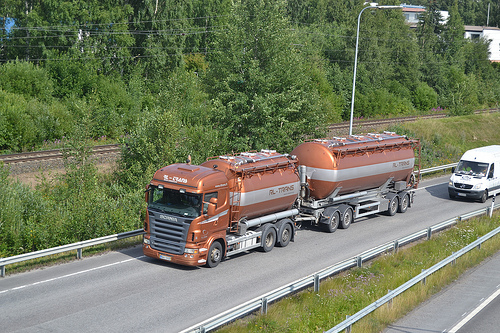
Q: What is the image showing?
A: It is showing a road.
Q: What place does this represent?
A: It represents the road.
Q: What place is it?
A: It is a road.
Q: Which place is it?
A: It is a road.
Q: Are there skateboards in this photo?
A: No, there are no skateboards.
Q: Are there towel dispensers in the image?
A: No, there are no towel dispensers.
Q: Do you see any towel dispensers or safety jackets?
A: No, there are no towel dispensers or safety jackets.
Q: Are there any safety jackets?
A: No, there are no safety jackets.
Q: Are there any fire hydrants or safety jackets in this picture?
A: No, there are no safety jackets or fire hydrants.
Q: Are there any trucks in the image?
A: Yes, there is a truck.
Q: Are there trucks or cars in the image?
A: Yes, there is a truck.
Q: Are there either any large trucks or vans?
A: Yes, there is a large truck.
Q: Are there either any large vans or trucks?
A: Yes, there is a large truck.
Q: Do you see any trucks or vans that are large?
A: Yes, the truck is large.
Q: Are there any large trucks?
A: Yes, there is a large truck.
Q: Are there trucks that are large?
A: Yes, there is a truck that is large.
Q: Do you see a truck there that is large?
A: Yes, there is a truck that is large.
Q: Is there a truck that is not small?
A: Yes, there is a large truck.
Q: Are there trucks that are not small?
A: Yes, there is a large truck.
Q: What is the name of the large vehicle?
A: The vehicle is a truck.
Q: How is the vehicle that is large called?
A: The vehicle is a truck.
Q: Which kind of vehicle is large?
A: The vehicle is a truck.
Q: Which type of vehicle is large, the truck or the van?
A: The truck is large.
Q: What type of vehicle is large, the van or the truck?
A: The truck is large.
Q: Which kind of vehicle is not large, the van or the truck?
A: The van is not large.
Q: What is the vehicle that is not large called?
A: The vehicle is a van.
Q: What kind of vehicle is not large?
A: The vehicle is a van.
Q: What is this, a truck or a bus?
A: This is a truck.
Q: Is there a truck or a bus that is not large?
A: No, there is a truck but it is large.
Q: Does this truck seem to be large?
A: Yes, the truck is large.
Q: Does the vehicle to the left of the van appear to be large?
A: Yes, the truck is large.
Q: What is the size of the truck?
A: The truck is large.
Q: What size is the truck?
A: The truck is large.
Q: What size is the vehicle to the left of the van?
A: The truck is large.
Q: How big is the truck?
A: The truck is large.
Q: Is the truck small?
A: No, the truck is large.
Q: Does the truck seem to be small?
A: No, the truck is large.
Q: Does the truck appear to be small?
A: No, the truck is large.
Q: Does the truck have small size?
A: No, the truck is large.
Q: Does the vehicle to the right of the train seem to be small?
A: No, the truck is large.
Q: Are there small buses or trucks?
A: No, there is a truck but it is large.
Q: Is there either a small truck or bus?
A: No, there is a truck but it is large.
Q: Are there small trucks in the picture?
A: No, there is a truck but it is large.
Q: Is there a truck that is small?
A: No, there is a truck but it is large.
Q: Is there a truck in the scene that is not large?
A: No, there is a truck but it is large.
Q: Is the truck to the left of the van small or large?
A: The truck is large.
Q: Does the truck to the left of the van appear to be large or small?
A: The truck is large.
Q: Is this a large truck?
A: Yes, this is a large truck.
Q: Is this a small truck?
A: No, this is a large truck.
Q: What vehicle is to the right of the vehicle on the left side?
A: The vehicle is a truck.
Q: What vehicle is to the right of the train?
A: The vehicle is a truck.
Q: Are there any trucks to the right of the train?
A: Yes, there is a truck to the right of the train.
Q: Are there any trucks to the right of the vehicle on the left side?
A: Yes, there is a truck to the right of the train.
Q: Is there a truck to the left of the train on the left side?
A: No, the truck is to the right of the train.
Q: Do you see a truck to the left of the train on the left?
A: No, the truck is to the right of the train.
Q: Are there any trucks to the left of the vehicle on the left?
A: No, the truck is to the right of the train.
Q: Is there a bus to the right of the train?
A: No, there is a truck to the right of the train.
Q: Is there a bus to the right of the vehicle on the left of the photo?
A: No, there is a truck to the right of the train.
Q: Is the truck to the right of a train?
A: Yes, the truck is to the right of a train.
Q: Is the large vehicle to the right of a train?
A: Yes, the truck is to the right of a train.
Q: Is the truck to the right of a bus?
A: No, the truck is to the right of a train.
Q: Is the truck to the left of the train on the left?
A: No, the truck is to the right of the train.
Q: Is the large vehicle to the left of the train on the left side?
A: No, the truck is to the right of the train.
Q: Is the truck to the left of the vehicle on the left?
A: No, the truck is to the right of the train.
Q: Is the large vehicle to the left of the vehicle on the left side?
A: No, the truck is to the right of the train.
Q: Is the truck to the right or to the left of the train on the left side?
A: The truck is to the right of the train.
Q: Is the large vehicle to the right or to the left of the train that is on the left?
A: The truck is to the right of the train.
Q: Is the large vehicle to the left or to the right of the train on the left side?
A: The truck is to the right of the train.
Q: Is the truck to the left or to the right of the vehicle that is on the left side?
A: The truck is to the right of the train.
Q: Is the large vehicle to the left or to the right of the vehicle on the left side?
A: The truck is to the right of the train.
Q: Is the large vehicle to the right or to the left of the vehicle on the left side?
A: The truck is to the right of the train.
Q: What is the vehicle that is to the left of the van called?
A: The vehicle is a truck.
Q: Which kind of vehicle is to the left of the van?
A: The vehicle is a truck.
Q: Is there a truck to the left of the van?
A: Yes, there is a truck to the left of the van.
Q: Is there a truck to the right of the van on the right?
A: No, the truck is to the left of the van.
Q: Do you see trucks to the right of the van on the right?
A: No, the truck is to the left of the van.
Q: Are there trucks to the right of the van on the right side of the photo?
A: No, the truck is to the left of the van.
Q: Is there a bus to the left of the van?
A: No, there is a truck to the left of the van.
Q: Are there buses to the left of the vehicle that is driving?
A: No, there is a truck to the left of the van.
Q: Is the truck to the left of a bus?
A: No, the truck is to the left of the van.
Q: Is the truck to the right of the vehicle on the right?
A: No, the truck is to the left of the van.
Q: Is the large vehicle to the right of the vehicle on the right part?
A: No, the truck is to the left of the van.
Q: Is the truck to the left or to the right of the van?
A: The truck is to the left of the van.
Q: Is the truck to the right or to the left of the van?
A: The truck is to the left of the van.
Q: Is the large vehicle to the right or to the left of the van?
A: The truck is to the left of the van.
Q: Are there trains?
A: Yes, there is a train.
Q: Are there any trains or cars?
A: Yes, there is a train.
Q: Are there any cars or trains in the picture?
A: Yes, there is a train.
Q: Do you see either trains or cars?
A: Yes, there is a train.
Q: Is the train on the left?
A: Yes, the train is on the left of the image.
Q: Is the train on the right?
A: No, the train is on the left of the image.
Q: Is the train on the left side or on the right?
A: The train is on the left of the image.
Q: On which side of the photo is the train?
A: The train is on the left of the image.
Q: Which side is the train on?
A: The train is on the left of the image.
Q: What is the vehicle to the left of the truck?
A: The vehicle is a train.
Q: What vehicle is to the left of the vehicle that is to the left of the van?
A: The vehicle is a train.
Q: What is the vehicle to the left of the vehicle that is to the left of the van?
A: The vehicle is a train.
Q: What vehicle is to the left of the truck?
A: The vehicle is a train.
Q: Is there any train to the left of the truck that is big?
A: Yes, there is a train to the left of the truck.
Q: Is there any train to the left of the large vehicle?
A: Yes, there is a train to the left of the truck.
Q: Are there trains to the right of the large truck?
A: No, the train is to the left of the truck.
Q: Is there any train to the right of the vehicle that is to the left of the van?
A: No, the train is to the left of the truck.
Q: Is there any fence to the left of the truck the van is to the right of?
A: No, there is a train to the left of the truck.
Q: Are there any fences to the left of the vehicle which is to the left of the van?
A: No, there is a train to the left of the truck.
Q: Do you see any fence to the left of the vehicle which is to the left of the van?
A: No, there is a train to the left of the truck.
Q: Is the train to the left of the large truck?
A: Yes, the train is to the left of the truck.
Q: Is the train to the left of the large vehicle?
A: Yes, the train is to the left of the truck.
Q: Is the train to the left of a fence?
A: No, the train is to the left of the truck.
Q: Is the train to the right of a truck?
A: No, the train is to the left of a truck.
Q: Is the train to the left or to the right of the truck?
A: The train is to the left of the truck.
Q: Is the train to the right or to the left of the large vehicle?
A: The train is to the left of the truck.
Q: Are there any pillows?
A: No, there are no pillows.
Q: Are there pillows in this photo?
A: No, there are no pillows.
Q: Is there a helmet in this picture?
A: No, there are no helmets.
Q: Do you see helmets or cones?
A: No, there are no helmets or cones.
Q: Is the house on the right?
A: Yes, the house is on the right of the image.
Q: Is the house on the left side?
A: No, the house is on the right of the image.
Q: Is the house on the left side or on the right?
A: The house is on the right of the image.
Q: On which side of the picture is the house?
A: The house is on the right of the image.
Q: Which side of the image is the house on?
A: The house is on the right of the image.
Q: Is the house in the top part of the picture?
A: Yes, the house is in the top of the image.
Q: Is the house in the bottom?
A: No, the house is in the top of the image.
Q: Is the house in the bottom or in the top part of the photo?
A: The house is in the top of the image.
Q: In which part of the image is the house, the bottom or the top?
A: The house is in the top of the image.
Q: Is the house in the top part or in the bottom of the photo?
A: The house is in the top of the image.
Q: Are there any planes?
A: No, there are no planes.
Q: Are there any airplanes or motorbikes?
A: No, there are no airplanes or motorbikes.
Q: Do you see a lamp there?
A: Yes, there is a lamp.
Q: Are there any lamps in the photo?
A: Yes, there is a lamp.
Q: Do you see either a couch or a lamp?
A: Yes, there is a lamp.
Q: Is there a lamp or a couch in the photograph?
A: Yes, there is a lamp.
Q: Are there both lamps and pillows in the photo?
A: No, there is a lamp but no pillows.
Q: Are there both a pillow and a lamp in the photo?
A: No, there is a lamp but no pillows.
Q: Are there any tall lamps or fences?
A: Yes, there is a tall lamp.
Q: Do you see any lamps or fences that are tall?
A: Yes, the lamp is tall.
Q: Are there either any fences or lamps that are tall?
A: Yes, the lamp is tall.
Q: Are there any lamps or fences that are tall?
A: Yes, the lamp is tall.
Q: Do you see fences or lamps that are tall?
A: Yes, the lamp is tall.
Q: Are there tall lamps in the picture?
A: Yes, there is a tall lamp.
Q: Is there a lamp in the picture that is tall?
A: Yes, there is a lamp that is tall.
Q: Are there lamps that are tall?
A: Yes, there is a lamp that is tall.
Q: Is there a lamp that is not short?
A: Yes, there is a tall lamp.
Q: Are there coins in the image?
A: No, there are no coins.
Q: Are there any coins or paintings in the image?
A: No, there are no coins or paintings.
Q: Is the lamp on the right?
A: Yes, the lamp is on the right of the image.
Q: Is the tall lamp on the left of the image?
A: No, the lamp is on the right of the image.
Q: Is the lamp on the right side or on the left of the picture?
A: The lamp is on the right of the image.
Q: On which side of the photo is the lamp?
A: The lamp is on the right of the image.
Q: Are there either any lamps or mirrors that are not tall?
A: No, there is a lamp but it is tall.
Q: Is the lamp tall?
A: Yes, the lamp is tall.